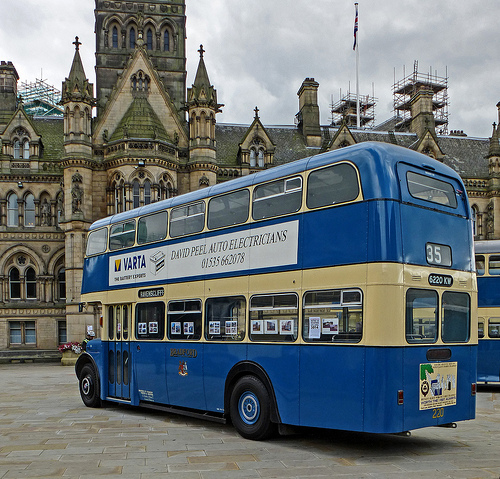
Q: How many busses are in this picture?
A: Two.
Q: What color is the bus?
A: Blue.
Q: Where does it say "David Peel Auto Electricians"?
A: On the bus.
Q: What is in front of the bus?
A: A building.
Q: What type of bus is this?
A: Double Decker.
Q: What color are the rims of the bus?
A: Blue.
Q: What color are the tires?
A: Black.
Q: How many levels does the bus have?
A: Two.